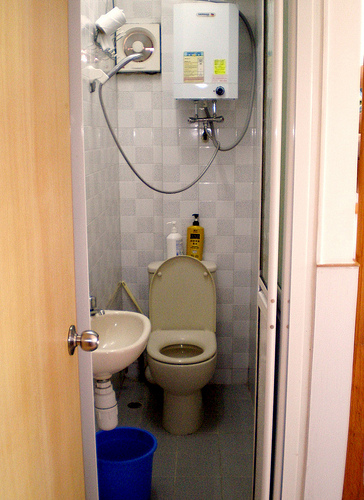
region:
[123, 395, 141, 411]
a drain in a bathroom floor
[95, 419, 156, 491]
a blue bucket under a sink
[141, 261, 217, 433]
a toilet in a bathroom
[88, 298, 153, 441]
a bathroom sink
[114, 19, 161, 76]
a fan on a bathroomwall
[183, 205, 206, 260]
a gold and black lotion bottle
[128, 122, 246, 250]
grey and white tile behind a toilet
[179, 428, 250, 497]
a grey bathroom tile floor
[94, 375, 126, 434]
a white pipe under a sink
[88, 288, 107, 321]
a faucet on a sink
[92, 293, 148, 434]
a white pedestal sink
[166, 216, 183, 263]
a white lotion bottle on the back of a toilet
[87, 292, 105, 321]
the faucet of a sink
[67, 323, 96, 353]
a doorknob on a door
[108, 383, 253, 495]
a tile bathroom floor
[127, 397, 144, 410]
a drain in a floor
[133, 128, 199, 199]
a tiled bathroom wall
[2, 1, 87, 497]
a wooden bathroom door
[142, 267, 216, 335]
Toilet lid is up.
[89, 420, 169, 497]
Blue bucket on the floor.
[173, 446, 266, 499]
Tile on the floor.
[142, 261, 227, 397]
The toilet is brown.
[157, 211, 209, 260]
Beauty products on the toilet tank.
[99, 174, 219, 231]
The wall is tiled.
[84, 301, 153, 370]
The sink is white.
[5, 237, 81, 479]
The door is brown.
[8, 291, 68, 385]
The door is wooden.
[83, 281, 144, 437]
Sink is connected to the wall.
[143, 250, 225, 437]
the toilet bowl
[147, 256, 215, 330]
the toilet seat lid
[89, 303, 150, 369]
the small white sink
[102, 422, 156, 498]
the blue bucket under the sink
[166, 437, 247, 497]
the tiled bathroom floor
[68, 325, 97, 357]
the silver door knob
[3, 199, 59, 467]
the wooden door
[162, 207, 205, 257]
the bottles on the toilet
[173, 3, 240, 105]
the white metal box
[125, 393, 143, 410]
the drain on the ground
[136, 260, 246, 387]
The lid to the toilet is up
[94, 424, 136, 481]
The bucket is blue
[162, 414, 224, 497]
The floor is tiled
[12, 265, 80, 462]
The door is wooden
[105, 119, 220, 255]
The wall is tiled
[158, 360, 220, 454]
The toilet is off white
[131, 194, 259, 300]
The bottles are on the back of the toilet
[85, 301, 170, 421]
The sink is empty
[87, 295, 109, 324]
The faucet is metal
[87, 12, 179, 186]
The shower is connected to the wall